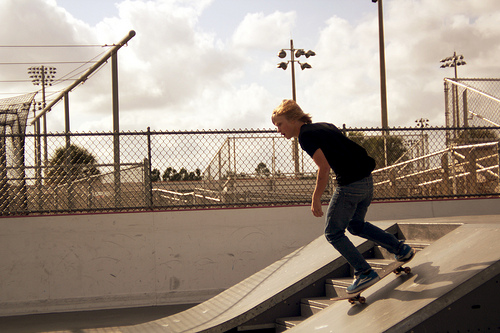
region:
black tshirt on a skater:
[295, 120, 379, 186]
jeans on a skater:
[323, 173, 402, 273]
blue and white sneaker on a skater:
[344, 263, 384, 297]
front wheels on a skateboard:
[342, 293, 369, 307]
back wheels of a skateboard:
[390, 265, 412, 276]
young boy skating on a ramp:
[267, 98, 441, 306]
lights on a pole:
[273, 37, 319, 175]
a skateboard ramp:
[55, 213, 398, 332]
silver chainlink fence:
[0, 123, 498, 215]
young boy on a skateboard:
[269, 98, 417, 305]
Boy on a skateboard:
[330, 243, 424, 306]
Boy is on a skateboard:
[327, 242, 415, 311]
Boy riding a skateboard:
[324, 247, 420, 308]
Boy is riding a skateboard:
[331, 245, 416, 308]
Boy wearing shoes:
[339, 241, 418, 295]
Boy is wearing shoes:
[332, 240, 419, 297]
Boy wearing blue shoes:
[348, 237, 415, 294]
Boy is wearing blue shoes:
[341, 241, 415, 295]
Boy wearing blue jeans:
[322, 170, 404, 273]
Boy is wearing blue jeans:
[321, 175, 410, 275]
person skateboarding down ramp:
[254, 93, 432, 311]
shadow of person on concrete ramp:
[343, 244, 496, 325]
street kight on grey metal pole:
[267, 31, 323, 179]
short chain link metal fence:
[2, 123, 499, 213]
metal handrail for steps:
[144, 181, 237, 212]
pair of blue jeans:
[320, 180, 409, 269]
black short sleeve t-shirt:
[289, 117, 380, 190]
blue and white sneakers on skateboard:
[340, 239, 418, 302]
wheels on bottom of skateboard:
[344, 258, 421, 305]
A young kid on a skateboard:
[256, 81, 429, 321]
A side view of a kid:
[266, 91, 423, 321]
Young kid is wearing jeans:
[313, 172, 419, 299]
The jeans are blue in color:
[303, 170, 409, 285]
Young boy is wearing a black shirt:
[283, 117, 385, 197]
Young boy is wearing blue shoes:
[329, 236, 436, 300]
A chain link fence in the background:
[0, 120, 498, 220]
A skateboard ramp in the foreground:
[68, 213, 496, 331]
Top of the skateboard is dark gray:
[325, 242, 420, 324]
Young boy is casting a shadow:
[344, 244, 499, 326]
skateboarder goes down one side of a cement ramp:
[271, 101, 419, 326]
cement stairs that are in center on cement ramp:
[131, 197, 499, 330]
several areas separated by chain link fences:
[11, 73, 499, 207]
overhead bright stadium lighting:
[24, 58, 56, 116]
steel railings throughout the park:
[363, 142, 498, 207]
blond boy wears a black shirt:
[267, 93, 376, 183]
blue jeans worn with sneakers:
[321, 167, 418, 296]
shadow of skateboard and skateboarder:
[343, 257, 481, 319]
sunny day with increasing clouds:
[0, 0, 497, 147]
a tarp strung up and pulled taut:
[1, 53, 63, 220]